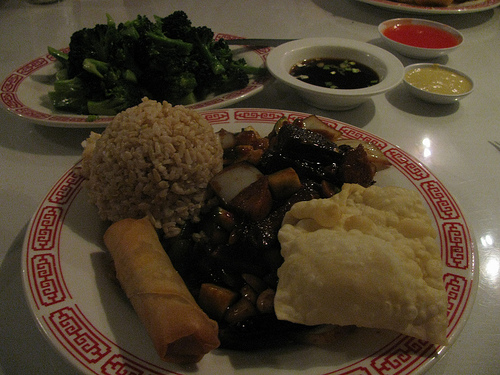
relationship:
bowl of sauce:
[286, 46, 383, 110] [290, 56, 380, 88]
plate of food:
[21, 117, 463, 361] [97, 140, 404, 329]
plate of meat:
[14, 104, 486, 375] [204, 138, 337, 307]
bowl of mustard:
[402, 60, 476, 108] [411, 69, 464, 96]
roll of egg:
[98, 213, 231, 369] [124, 243, 184, 317]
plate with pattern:
[21, 117, 463, 361] [375, 135, 464, 223]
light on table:
[472, 230, 499, 284] [6, 7, 494, 364]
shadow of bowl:
[283, 96, 396, 145] [267, 40, 399, 115]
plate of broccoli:
[8, 29, 242, 120] [59, 21, 226, 99]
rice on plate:
[84, 103, 213, 223] [21, 117, 463, 361]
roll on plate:
[98, 213, 231, 369] [21, 117, 463, 361]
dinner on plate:
[97, 140, 404, 329] [21, 117, 463, 361]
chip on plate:
[285, 188, 447, 333] [21, 117, 463, 361]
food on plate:
[97, 140, 404, 329] [21, 117, 463, 361]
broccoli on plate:
[59, 21, 226, 99] [8, 29, 242, 120]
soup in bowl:
[286, 46, 383, 110] [267, 40, 399, 115]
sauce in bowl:
[402, 60, 474, 104] [402, 60, 476, 108]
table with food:
[6, 7, 494, 364] [97, 140, 404, 329]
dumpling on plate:
[285, 188, 447, 333] [21, 117, 463, 361]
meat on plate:
[204, 138, 337, 307] [14, 104, 486, 375]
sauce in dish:
[286, 46, 383, 110] [267, 40, 399, 115]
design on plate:
[375, 135, 464, 223] [21, 117, 463, 361]